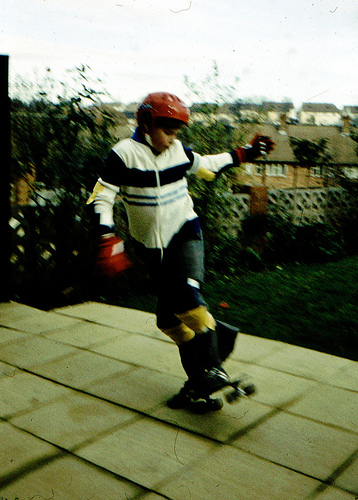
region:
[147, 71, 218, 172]
this is a helmet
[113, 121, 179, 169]
the helmet is red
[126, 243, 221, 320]
this is a picture of shorts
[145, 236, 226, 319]
the shorts are black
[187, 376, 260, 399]
This is a skateboard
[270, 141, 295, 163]
this is a roof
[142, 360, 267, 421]
these are some wheels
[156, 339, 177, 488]
this is a crack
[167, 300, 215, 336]
this is a yellow path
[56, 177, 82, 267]
this is an old tree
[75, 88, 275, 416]
A young boy doing a trick on his skateboard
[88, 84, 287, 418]
the boy is skateboarding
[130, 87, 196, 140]
boy wearing red helmet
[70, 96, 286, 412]
boy wearing red and black gloves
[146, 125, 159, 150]
white strap on helmet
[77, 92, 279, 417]
the boy is looking down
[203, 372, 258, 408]
top of skateboard off ground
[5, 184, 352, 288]
white fence in background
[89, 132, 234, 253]
boy's jacket is blue white and yellow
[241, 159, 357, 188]
house made of brick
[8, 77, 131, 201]
tree behind the fence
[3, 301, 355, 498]
back deck of a house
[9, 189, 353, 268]
fence on down the side of the backyard.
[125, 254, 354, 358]
green grass in backyard.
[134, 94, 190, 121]
red safety helmet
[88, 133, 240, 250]
white sweatshirt with blue stripes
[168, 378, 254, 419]
a skateboard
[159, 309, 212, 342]
skateboarder's yellow kneepads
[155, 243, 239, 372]
the skateboarder's clue jeans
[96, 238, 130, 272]
a red glove on his right hand.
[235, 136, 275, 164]
a red glove on his left hand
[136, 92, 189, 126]
Red helmet on boy's head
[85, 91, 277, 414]
Boy riding on skateboard on patio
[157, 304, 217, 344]
Yellow kneepads on boy's knees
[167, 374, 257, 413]
Skateboard's wheels up in the air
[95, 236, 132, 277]
Red glove on boy's hand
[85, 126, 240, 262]
Boy's long sleeved striped sweater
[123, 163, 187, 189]
Black stripe in middle of sweater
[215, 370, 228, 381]
White stripe on boy's shoe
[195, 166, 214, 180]
Yellow patch on boy's elbow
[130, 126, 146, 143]
Blue collar on boy's sweater